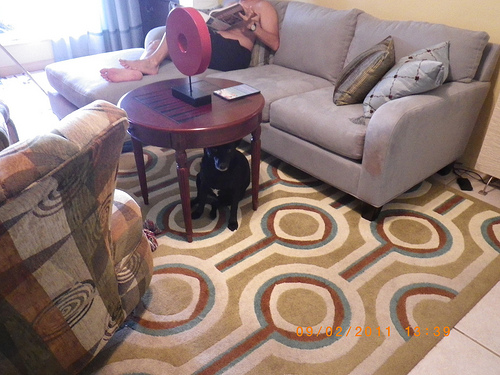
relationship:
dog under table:
[191, 148, 250, 232] [121, 73, 271, 223]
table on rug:
[131, 72, 268, 221] [186, 186, 428, 371]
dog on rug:
[191, 140, 251, 230] [85, 135, 498, 375]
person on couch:
[82, 0, 284, 82] [39, 0, 497, 208]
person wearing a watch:
[100, 0, 279, 83] [247, 20, 262, 35]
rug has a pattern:
[85, 135, 498, 375] [238, 260, 365, 362]